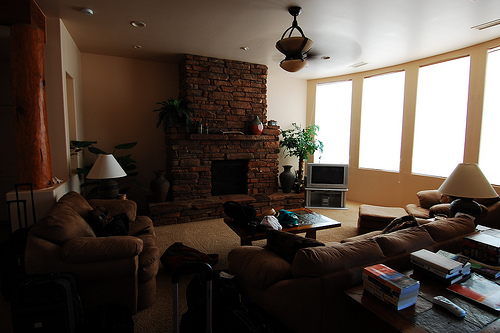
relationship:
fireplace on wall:
[157, 52, 299, 218] [152, 59, 311, 222]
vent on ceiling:
[472, 17, 499, 32] [4, 0, 495, 77]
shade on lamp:
[435, 161, 498, 201] [435, 161, 499, 231]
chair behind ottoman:
[403, 186, 470, 223] [355, 202, 408, 232]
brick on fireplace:
[225, 67, 241, 75] [145, 51, 307, 227]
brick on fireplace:
[174, 66, 309, 223] [155, 61, 307, 183]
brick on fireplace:
[190, 151, 200, 156] [204, 155, 253, 198]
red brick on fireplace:
[255, 157, 275, 180] [157, 92, 305, 217]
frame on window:
[300, 39, 498, 212] [311, 51, 431, 188]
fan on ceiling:
[235, 30, 360, 72] [49, 2, 496, 79]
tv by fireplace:
[306, 162, 349, 188] [169, 132, 278, 196]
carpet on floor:
[173, 220, 222, 246] [139, 199, 356, 329]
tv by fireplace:
[303, 162, 348, 184] [181, 142, 276, 191]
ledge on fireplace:
[166, 130, 282, 141] [166, 94, 292, 186]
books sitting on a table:
[356, 255, 420, 319] [295, 224, 493, 306]